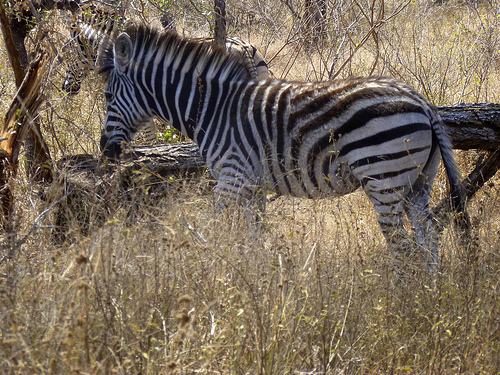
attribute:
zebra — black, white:
[94, 30, 467, 292]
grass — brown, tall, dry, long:
[70, 233, 474, 375]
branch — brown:
[10, 41, 60, 163]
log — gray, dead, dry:
[62, 97, 498, 198]